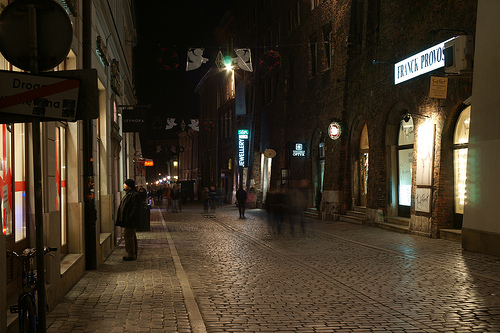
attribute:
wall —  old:
[331, 54, 391, 116]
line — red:
[3, 82, 75, 99]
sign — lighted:
[389, 39, 453, 88]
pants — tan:
[109, 216, 173, 273]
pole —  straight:
[83, 2, 98, 273]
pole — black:
[79, 1, 101, 271]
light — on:
[219, 56, 234, 71]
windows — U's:
[350, 123, 371, 210]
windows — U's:
[389, 101, 421, 217]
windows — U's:
[444, 107, 476, 230]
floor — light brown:
[172, 226, 499, 330]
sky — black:
[134, 11, 186, 114]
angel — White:
[187, 50, 201, 73]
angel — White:
[226, 44, 256, 76]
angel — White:
[160, 112, 174, 134]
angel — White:
[183, 113, 200, 134]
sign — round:
[1, 0, 93, 318]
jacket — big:
[116, 188, 143, 225]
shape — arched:
[381, 97, 421, 230]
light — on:
[266, 151, 275, 169]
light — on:
[400, 113, 420, 133]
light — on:
[424, 104, 444, 129]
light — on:
[257, 150, 267, 166]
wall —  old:
[291, 10, 347, 215]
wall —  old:
[209, 33, 254, 207]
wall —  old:
[86, 0, 146, 276]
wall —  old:
[0, 6, 45, 327]